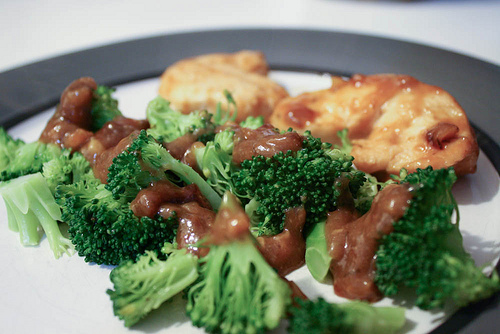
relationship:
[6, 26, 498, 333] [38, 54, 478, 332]
plate with food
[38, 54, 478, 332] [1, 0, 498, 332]
food on table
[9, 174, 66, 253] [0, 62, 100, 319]
broccoli stem on plate edge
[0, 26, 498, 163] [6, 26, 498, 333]
edge lining on plate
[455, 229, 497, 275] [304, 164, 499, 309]
shadow of broccoli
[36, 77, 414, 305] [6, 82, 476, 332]
brown sauce on broccoli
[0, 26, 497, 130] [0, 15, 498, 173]
edge on plate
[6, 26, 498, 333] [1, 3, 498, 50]
plate on counter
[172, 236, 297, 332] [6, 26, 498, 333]
broccoli on plate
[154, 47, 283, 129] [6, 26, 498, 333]
meat on plate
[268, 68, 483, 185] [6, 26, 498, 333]
meat on plate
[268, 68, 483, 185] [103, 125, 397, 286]
meat next to broccoli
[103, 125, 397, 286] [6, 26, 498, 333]
broccoli on plate